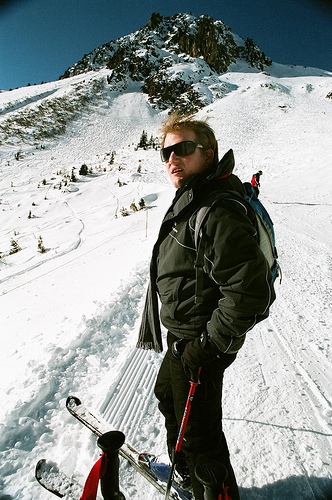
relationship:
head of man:
[160, 117, 221, 190] [155, 113, 275, 500]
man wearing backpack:
[155, 113, 275, 500] [229, 178, 289, 284]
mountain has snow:
[40, 14, 321, 227] [17, 64, 321, 159]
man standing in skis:
[155, 113, 275, 500] [34, 393, 169, 498]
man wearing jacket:
[155, 113, 275, 500] [159, 153, 276, 359]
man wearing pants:
[155, 113, 275, 500] [159, 334, 241, 492]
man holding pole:
[155, 113, 275, 500] [164, 350, 205, 496]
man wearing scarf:
[155, 113, 275, 500] [135, 145, 235, 349]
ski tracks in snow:
[82, 334, 167, 461] [0, 56, 330, 496]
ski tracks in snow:
[1, 191, 86, 283] [0, 56, 330, 496]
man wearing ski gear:
[155, 113, 275, 500] [136, 147, 282, 498]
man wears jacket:
[155, 113, 275, 500] [146, 174, 283, 357]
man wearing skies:
[155, 113, 275, 500] [34, 392, 129, 496]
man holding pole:
[139, 118, 241, 495] [161, 382, 201, 500]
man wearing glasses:
[155, 113, 275, 500] [156, 138, 201, 160]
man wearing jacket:
[155, 113, 275, 500] [156, 183, 252, 347]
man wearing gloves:
[155, 113, 275, 500] [179, 328, 222, 374]